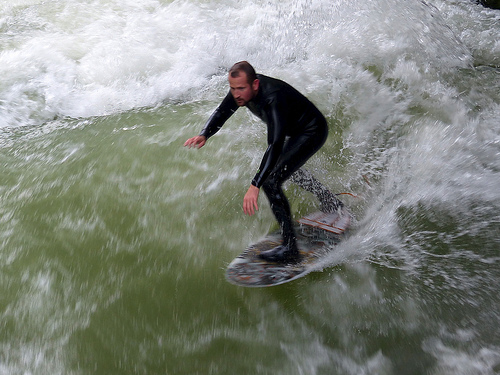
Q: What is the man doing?
A: Surfing a wave.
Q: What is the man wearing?
A: Black wetsuit.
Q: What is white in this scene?
A: A wave.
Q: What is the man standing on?
A: A surfboard.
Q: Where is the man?
A: In the ocean.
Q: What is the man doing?
A: Surfing.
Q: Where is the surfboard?
A: In the water.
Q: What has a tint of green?
A: The water.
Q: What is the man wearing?
A: Wetsuit.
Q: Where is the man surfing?
A: Ocean.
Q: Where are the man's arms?
A: In front.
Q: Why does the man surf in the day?
A: So can see.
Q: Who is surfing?
A: A man.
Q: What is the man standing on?
A: A surfboard.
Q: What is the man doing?
A: Surfing.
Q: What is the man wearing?
A: A wetsuit.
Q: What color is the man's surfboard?
A: Red, black and white.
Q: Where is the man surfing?
A: In the ocean.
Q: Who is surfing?
A: A man.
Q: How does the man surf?
A: He balances on the board.